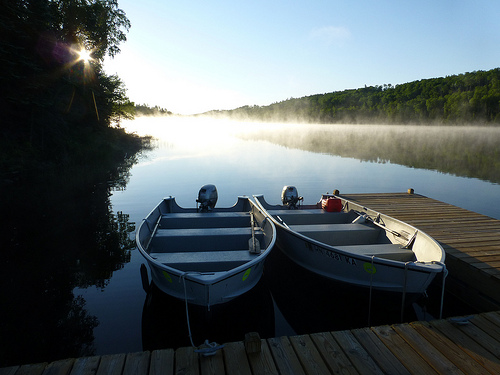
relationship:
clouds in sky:
[165, 81, 235, 113] [162, 29, 269, 81]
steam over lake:
[158, 99, 346, 158] [177, 105, 391, 180]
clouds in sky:
[165, 88, 199, 112] [98, 0, 498, 115]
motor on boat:
[192, 179, 224, 213] [128, 176, 284, 328]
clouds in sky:
[306, 18, 354, 50] [98, 0, 498, 115]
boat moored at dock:
[253, 188, 453, 307] [0, 189, 500, 374]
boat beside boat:
[253, 188, 453, 307] [131, 180, 272, 313]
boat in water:
[253, 188, 453, 307] [137, 115, 420, 189]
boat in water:
[131, 180, 272, 313] [137, 115, 420, 189]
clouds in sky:
[306, 25, 356, 50] [86, 0, 441, 63]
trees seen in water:
[2, 1, 154, 373] [80, 113, 497, 290]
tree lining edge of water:
[190, 70, 499, 125] [6, 109, 498, 190]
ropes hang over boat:
[175, 267, 469, 338] [252, 185, 447, 298]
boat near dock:
[252, 185, 447, 298] [14, 331, 498, 373]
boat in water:
[131, 180, 272, 313] [0, 110, 499, 364]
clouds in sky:
[306, 25, 356, 50] [98, 0, 498, 115]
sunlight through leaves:
[45, 27, 105, 95] [55, 0, 129, 72]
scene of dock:
[4, 99, 498, 371] [0, 189, 500, 374]